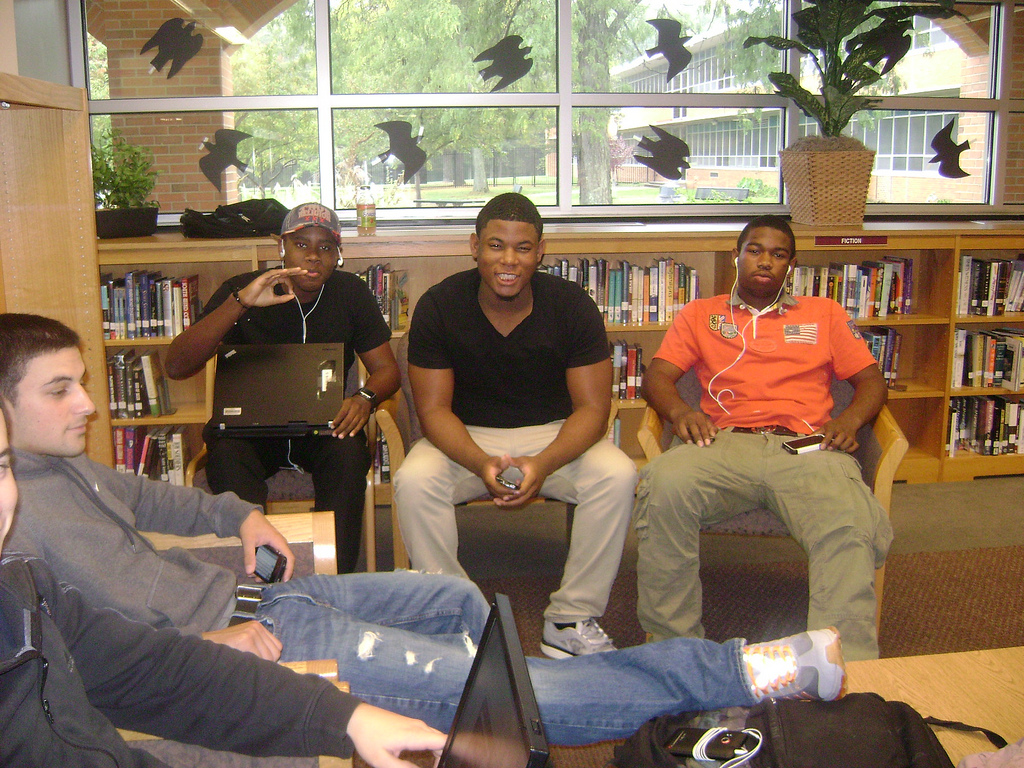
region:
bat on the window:
[114, 6, 225, 80]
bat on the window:
[469, 38, 531, 87]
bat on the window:
[611, 0, 697, 76]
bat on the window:
[588, 110, 694, 174]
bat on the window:
[917, 113, 975, 189]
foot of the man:
[501, 607, 607, 659]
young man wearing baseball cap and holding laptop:
[162, 200, 401, 571]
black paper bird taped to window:
[321, 93, 577, 220]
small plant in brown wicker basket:
[744, 3, 978, 229]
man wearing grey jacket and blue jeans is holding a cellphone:
[0, 308, 851, 748]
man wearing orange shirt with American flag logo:
[633, 213, 894, 662]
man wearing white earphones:
[631, 216, 897, 662]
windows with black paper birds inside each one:
[69, 1, 1015, 229]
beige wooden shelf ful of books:
[96, 216, 1023, 514]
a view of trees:
[379, 91, 515, 200]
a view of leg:
[256, 603, 495, 766]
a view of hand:
[334, 729, 407, 759]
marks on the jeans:
[318, 556, 459, 680]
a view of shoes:
[528, 566, 710, 728]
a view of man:
[615, 179, 935, 527]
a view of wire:
[685, 363, 762, 433]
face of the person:
[363, 160, 569, 288]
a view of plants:
[395, 66, 566, 161]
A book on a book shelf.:
[613, 260, 626, 318]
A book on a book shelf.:
[629, 267, 646, 325]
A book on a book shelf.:
[648, 266, 662, 333]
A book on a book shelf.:
[626, 345, 637, 403]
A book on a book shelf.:
[180, 279, 201, 321]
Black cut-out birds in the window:
[116, 19, 977, 194]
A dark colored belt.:
[214, 566, 260, 633]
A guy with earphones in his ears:
[621, 228, 926, 700]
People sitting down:
[2, 190, 939, 766]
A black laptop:
[213, 342, 350, 447]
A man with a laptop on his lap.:
[182, 184, 399, 628]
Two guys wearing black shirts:
[200, 180, 654, 634]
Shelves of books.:
[68, 221, 1018, 497]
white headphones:
[710, 249, 806, 436]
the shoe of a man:
[728, 620, 855, 707]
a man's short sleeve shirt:
[400, 272, 616, 431]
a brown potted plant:
[751, 2, 963, 236]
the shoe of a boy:
[532, 608, 621, 660]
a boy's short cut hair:
[2, 305, 80, 401]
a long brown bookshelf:
[87, 212, 1020, 506]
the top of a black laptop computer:
[397, 591, 547, 766]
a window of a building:
[569, 104, 791, 200]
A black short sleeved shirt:
[397, 257, 623, 435]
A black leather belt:
[212, 557, 271, 647]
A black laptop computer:
[190, 321, 356, 451]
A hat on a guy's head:
[263, 188, 353, 300]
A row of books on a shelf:
[80, 256, 213, 355]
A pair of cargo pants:
[611, 415, 902, 673]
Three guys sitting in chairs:
[146, 165, 921, 677]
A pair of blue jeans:
[256, 551, 769, 752]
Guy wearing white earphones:
[260, 217, 349, 348]